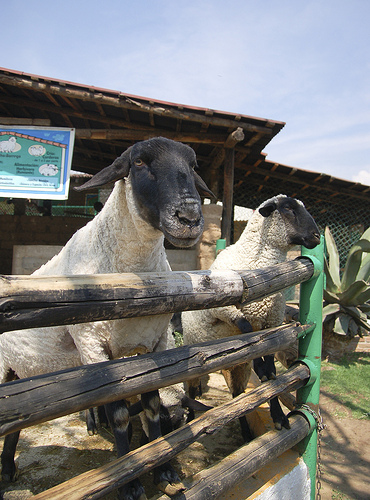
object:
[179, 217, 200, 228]
nostrils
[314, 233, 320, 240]
nostrils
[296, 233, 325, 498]
green post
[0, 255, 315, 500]
fence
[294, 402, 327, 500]
chain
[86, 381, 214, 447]
sheep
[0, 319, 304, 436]
fence post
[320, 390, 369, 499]
shadow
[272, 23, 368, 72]
sky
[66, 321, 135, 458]
legs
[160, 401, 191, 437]
sheep face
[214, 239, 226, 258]
post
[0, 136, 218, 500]
sheep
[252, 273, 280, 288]
wooden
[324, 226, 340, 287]
large leaves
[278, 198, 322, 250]
face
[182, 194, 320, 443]
sheep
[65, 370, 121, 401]
wood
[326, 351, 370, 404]
grass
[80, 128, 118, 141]
wood pen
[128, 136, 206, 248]
sheep head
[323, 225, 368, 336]
plant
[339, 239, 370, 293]
leaf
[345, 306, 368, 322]
leaf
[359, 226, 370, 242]
leaf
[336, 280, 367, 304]
leaf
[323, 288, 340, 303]
leaf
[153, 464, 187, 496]
foot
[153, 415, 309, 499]
pole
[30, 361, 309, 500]
post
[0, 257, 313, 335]
bar holder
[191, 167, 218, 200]
ears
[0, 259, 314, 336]
post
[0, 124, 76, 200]
sign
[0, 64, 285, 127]
roof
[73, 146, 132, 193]
ear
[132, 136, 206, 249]
face